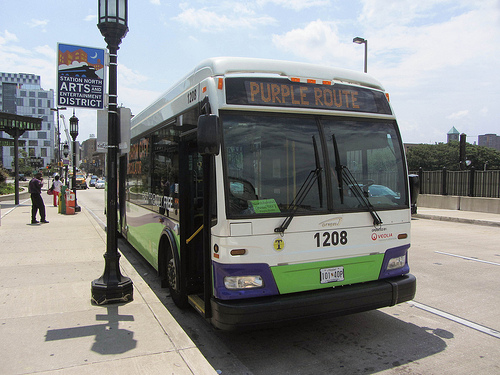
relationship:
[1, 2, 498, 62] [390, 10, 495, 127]
sky with clouds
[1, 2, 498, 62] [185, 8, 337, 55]
sky with clouds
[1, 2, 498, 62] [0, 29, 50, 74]
sky with clouds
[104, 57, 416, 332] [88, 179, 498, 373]
bus on street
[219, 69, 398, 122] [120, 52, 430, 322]
sign on bus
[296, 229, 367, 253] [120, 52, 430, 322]
number on bus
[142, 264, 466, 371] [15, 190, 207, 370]
shadow on ground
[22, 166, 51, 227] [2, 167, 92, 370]
man on side walk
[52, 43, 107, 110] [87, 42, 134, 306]
sign on pole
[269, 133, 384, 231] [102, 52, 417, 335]
wiper on bus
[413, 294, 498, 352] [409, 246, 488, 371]
line on road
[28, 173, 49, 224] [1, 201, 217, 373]
man on sidewalk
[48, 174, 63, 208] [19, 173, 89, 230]
lady on street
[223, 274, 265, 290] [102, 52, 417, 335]
headlight on bus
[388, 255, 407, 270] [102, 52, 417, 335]
headlight on bus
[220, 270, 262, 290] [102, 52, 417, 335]
headlight on bus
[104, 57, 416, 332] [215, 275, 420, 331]
bus has bumper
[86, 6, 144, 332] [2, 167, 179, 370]
lamp post on side walk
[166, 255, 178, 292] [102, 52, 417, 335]
wheel on bus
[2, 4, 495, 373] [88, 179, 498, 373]
city has street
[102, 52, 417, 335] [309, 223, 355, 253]
bus number 1208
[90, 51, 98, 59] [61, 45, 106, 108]
moon on sign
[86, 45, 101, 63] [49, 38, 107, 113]
moon on sign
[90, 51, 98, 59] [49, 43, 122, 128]
moon in corner of sign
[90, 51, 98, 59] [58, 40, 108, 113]
moon in corner of sign.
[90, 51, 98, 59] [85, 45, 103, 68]
moon in corner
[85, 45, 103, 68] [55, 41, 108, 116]
corner of sign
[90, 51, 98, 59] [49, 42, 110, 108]
moon in corner of sign